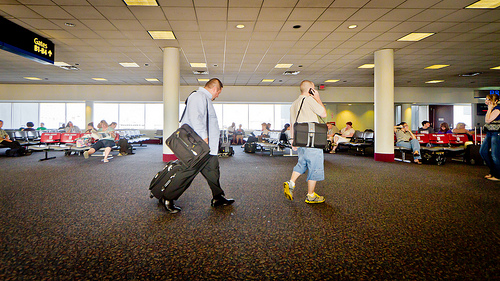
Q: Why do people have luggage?
A: To carry their belongings.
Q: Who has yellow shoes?
A: The man.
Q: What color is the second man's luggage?
A: Black.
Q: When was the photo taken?
A: Daytime.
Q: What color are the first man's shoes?
A: Yellow.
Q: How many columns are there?
A: Two.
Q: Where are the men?
A: The airport.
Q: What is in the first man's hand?
A: A phone.